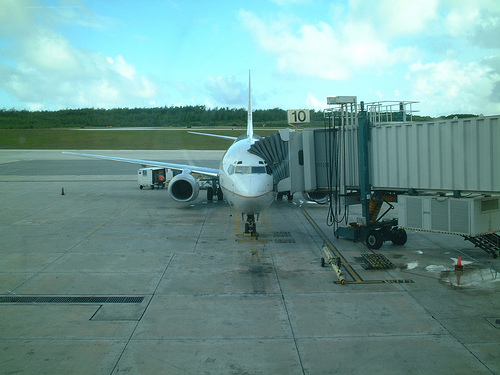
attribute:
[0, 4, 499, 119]
sky — blue, cloudy 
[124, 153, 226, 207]
van — white 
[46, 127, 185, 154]
field — large 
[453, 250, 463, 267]
cone — orange 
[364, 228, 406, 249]
two wheels — black 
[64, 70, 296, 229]
plane — large 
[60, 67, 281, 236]
airplane — docked